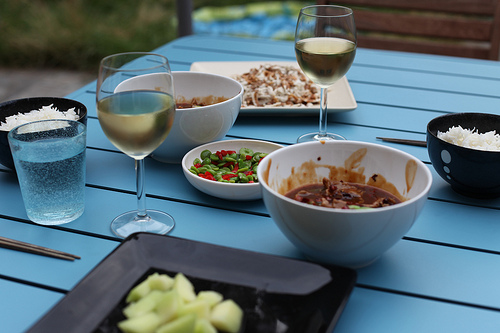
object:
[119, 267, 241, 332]
food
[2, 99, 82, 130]
rice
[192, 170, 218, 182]
peppers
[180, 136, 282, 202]
bowl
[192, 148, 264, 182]
vegetables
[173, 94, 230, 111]
food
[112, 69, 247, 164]
bowl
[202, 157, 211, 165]
beans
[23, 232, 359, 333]
plate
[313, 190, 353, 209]
pork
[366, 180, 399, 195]
sauce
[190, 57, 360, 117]
plate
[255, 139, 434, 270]
bowl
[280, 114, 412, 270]
white bowl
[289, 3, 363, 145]
glass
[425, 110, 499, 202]
bowl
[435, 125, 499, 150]
rice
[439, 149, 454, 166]
circles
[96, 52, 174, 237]
wine glass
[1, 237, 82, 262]
chopsticks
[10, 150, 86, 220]
water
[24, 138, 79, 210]
water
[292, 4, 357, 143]
glass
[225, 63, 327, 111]
dish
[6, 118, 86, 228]
glass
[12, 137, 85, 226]
water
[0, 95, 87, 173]
bowl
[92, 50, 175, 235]
glass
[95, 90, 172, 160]
wine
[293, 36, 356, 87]
wine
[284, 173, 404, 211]
gravy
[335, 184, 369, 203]
meat